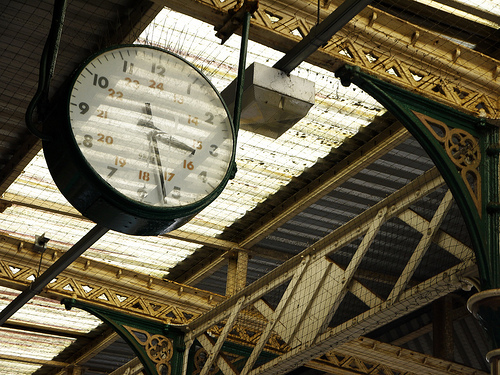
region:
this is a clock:
[41, 36, 246, 231]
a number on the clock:
[193, 99, 225, 132]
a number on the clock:
[206, 142, 225, 160]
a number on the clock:
[187, 160, 220, 192]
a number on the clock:
[170, 182, 189, 207]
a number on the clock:
[133, 178, 159, 212]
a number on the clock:
[106, 158, 125, 186]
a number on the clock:
[82, 130, 101, 151]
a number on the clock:
[76, 96, 95, 137]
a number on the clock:
[84, 65, 114, 96]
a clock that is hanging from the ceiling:
[60, 28, 274, 267]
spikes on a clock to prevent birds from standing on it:
[30, 24, 271, 89]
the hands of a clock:
[137, 95, 204, 215]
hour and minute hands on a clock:
[118, 81, 228, 208]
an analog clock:
[56, 26, 289, 238]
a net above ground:
[0, 41, 491, 330]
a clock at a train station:
[34, 22, 301, 268]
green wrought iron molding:
[340, 63, 499, 274]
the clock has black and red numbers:
[65, 44, 244, 235]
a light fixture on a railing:
[216, 56, 326, 146]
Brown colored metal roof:
[393, 33, 495, 103]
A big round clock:
[63, 44, 227, 207]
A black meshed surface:
[363, 210, 445, 282]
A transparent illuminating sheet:
[258, 146, 300, 175]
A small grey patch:
[253, 78, 317, 123]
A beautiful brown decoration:
[437, 121, 484, 163]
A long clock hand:
[152, 133, 172, 204]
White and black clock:
[36, 45, 242, 234]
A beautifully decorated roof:
[76, 264, 476, 369]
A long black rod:
[13, 231, 105, 311]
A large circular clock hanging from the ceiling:
[52, 38, 249, 244]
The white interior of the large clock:
[70, 48, 233, 208]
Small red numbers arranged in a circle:
[100, 73, 209, 186]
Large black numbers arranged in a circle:
[72, 50, 234, 207]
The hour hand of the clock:
[135, 112, 199, 166]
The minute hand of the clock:
[136, 90, 181, 212]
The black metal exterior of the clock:
[47, 38, 225, 231]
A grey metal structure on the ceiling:
[230, 62, 319, 141]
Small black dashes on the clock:
[122, 40, 189, 71]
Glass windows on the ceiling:
[158, 13, 374, 133]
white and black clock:
[49, 33, 264, 237]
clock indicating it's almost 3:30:
[60, 27, 250, 234]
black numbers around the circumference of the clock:
[61, 47, 246, 222]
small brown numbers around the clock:
[80, 68, 212, 188]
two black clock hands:
[139, 101, 205, 199]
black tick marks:
[124, 46, 163, 61]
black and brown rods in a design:
[342, 61, 499, 271]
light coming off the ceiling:
[25, 15, 383, 271]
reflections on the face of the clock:
[100, 73, 212, 190]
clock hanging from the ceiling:
[17, 2, 278, 262]